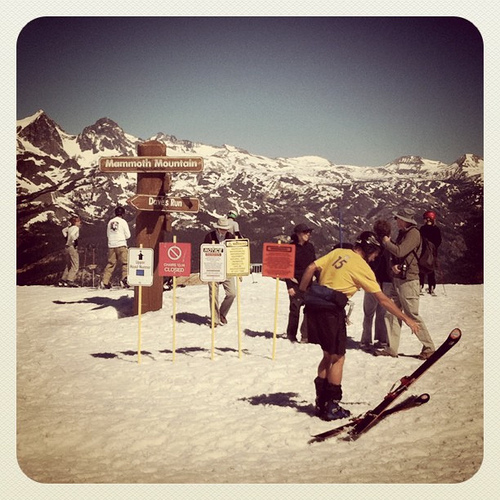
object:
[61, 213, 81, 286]
people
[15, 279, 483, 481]
snow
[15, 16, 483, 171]
sky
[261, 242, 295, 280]
banner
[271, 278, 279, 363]
pole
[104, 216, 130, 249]
t-shirt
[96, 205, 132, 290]
man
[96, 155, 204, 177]
destination signs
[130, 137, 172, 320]
brown column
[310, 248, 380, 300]
shirt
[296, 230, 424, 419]
man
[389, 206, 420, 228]
hat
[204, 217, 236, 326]
person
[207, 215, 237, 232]
hat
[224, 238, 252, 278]
sign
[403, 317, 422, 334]
hand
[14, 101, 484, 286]
mountain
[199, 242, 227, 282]
signs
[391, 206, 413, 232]
head